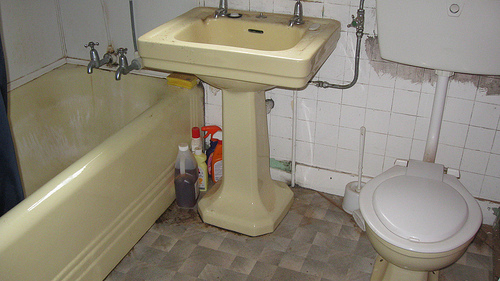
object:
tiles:
[312, 99, 346, 129]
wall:
[157, 0, 500, 225]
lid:
[370, 175, 471, 244]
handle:
[82, 39, 101, 49]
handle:
[112, 45, 128, 56]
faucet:
[111, 47, 138, 81]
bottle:
[172, 142, 203, 209]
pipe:
[421, 69, 458, 163]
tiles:
[284, 237, 315, 259]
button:
[447, 3, 461, 16]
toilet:
[338, 0, 500, 280]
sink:
[167, 16, 310, 55]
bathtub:
[0, 63, 210, 281]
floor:
[95, 167, 493, 280]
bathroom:
[0, 0, 500, 280]